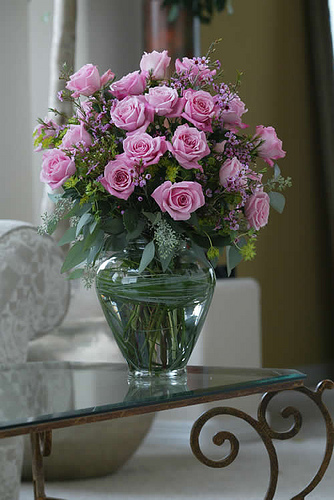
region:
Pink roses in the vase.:
[31, 48, 294, 273]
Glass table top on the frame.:
[1, 357, 306, 435]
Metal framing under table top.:
[0, 371, 331, 497]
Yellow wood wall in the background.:
[198, 2, 332, 375]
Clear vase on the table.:
[86, 233, 218, 377]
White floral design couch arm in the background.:
[0, 211, 70, 494]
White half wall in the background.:
[204, 278, 259, 435]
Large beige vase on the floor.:
[20, 309, 154, 486]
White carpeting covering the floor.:
[20, 376, 331, 496]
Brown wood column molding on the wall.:
[139, 1, 201, 86]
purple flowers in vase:
[40, 61, 267, 255]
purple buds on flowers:
[176, 58, 230, 109]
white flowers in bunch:
[51, 192, 185, 252]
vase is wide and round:
[113, 247, 200, 377]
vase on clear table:
[80, 231, 190, 362]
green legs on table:
[205, 379, 331, 483]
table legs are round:
[189, 385, 332, 484]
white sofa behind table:
[0, 253, 116, 382]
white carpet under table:
[131, 452, 212, 497]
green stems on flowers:
[120, 275, 194, 357]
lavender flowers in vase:
[68, 36, 255, 240]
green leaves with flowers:
[56, 126, 254, 224]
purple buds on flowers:
[188, 40, 241, 115]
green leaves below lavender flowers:
[47, 199, 163, 273]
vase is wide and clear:
[94, 243, 226, 385]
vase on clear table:
[92, 266, 232, 370]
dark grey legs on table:
[233, 370, 333, 476]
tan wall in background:
[208, 17, 315, 224]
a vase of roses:
[31, 37, 292, 382]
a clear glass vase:
[94, 237, 217, 384]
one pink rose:
[151, 179, 206, 220]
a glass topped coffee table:
[0, 361, 331, 494]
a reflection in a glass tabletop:
[121, 381, 186, 390]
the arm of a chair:
[0, 217, 67, 337]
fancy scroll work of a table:
[187, 384, 327, 492]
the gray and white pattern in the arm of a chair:
[0, 220, 66, 357]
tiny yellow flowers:
[234, 232, 256, 256]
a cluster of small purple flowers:
[226, 131, 251, 160]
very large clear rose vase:
[93, 235, 216, 388]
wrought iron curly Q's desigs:
[188, 376, 332, 498]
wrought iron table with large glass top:
[0, 359, 333, 498]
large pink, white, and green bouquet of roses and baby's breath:
[30, 35, 292, 289]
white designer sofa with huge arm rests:
[0, 218, 72, 498]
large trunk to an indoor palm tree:
[39, 0, 78, 252]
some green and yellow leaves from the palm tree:
[157, 0, 232, 30]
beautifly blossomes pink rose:
[150, 180, 205, 221]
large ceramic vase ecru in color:
[21, 255, 156, 481]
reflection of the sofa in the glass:
[0, 360, 74, 427]